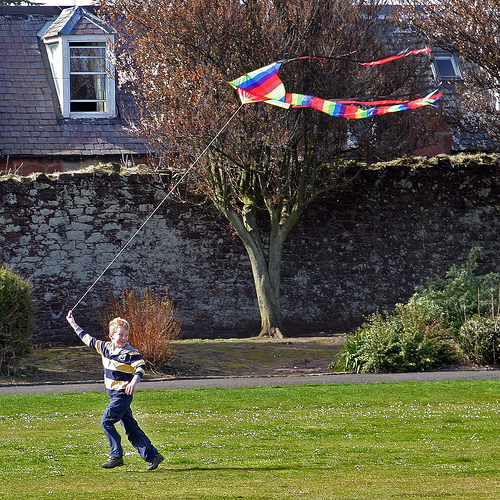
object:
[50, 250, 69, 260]
rock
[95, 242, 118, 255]
rock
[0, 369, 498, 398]
path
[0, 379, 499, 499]
field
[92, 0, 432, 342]
tree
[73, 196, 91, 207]
rock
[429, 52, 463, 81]
skylight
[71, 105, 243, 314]
string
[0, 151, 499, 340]
stone wall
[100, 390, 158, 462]
jeans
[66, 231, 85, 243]
rock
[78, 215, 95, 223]
rock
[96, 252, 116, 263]
rock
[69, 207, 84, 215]
rock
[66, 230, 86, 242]
grey rock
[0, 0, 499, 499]
scene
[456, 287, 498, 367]
bush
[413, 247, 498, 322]
bush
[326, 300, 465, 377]
bush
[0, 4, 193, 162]
roof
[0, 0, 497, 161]
house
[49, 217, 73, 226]
rock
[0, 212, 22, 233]
rock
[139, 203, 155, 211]
rock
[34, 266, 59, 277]
rock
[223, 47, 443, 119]
kite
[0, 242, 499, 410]
plants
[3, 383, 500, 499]
grass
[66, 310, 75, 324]
hand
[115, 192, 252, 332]
stone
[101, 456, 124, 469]
black shoe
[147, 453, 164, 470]
black shoe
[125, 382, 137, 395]
hand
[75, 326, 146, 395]
shirt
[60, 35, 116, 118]
window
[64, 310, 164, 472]
boy